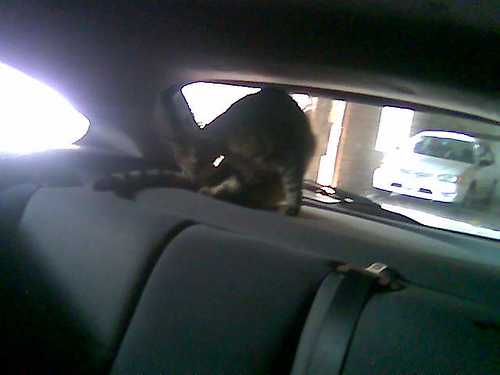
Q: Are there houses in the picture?
A: No, there are no houses.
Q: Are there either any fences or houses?
A: No, there are no houses or fences.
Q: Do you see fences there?
A: No, there are no fences.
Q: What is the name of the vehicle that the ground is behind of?
A: The vehicle is a car.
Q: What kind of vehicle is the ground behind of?
A: The ground is behind the car.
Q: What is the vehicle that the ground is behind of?
A: The vehicle is a car.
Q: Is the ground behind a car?
A: Yes, the ground is behind a car.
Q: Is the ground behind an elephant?
A: No, the ground is behind a car.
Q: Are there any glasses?
A: No, there are no glasses.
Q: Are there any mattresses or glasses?
A: No, there are no glasses or mattresses.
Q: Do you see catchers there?
A: No, there are no catchers.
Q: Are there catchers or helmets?
A: No, there are no catchers or helmets.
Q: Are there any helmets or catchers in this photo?
A: No, there are no catchers or helmets.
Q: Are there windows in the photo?
A: Yes, there is a window.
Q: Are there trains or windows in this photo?
A: Yes, there is a window.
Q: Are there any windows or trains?
A: Yes, there is a window.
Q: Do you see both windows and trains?
A: No, there is a window but no trains.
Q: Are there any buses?
A: No, there are no buses.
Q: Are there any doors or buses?
A: No, there are no buses or doors.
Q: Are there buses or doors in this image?
A: No, there are no buses or doors.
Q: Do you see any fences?
A: No, there are no fences.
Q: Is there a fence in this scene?
A: No, there are no fences.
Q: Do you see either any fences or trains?
A: No, there are no fences or trains.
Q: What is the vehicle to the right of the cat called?
A: The vehicle is a car.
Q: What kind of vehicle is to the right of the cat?
A: The vehicle is a car.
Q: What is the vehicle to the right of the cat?
A: The vehicle is a car.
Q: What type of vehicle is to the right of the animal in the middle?
A: The vehicle is a car.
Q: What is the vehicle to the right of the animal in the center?
A: The vehicle is a car.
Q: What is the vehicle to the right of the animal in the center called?
A: The vehicle is a car.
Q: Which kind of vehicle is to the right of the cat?
A: The vehicle is a car.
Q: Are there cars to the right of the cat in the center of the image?
A: Yes, there is a car to the right of the cat.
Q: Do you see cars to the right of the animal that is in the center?
A: Yes, there is a car to the right of the cat.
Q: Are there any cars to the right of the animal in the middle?
A: Yes, there is a car to the right of the cat.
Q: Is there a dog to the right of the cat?
A: No, there is a car to the right of the cat.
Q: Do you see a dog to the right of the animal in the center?
A: No, there is a car to the right of the cat.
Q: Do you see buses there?
A: No, there are no buses.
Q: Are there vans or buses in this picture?
A: No, there are no buses or vans.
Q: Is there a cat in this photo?
A: Yes, there is a cat.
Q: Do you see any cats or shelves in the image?
A: Yes, there is a cat.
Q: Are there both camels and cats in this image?
A: No, there is a cat but no camels.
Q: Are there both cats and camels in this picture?
A: No, there is a cat but no camels.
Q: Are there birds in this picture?
A: No, there are no birds.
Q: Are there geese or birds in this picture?
A: No, there are no birds or geese.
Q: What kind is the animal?
A: The animal is a cat.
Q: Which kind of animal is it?
A: The animal is a cat.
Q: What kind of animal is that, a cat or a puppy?
A: This is a cat.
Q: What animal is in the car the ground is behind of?
A: The cat is in the car.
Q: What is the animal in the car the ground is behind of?
A: The animal is a cat.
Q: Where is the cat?
A: The cat is in the car.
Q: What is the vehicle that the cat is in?
A: The vehicle is a car.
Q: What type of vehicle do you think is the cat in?
A: The cat is in the car.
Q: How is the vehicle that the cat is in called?
A: The vehicle is a car.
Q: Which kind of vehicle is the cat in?
A: The cat is in the car.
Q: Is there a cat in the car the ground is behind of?
A: Yes, there is a cat in the car.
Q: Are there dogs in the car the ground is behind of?
A: No, there is a cat in the car.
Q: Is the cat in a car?
A: Yes, the cat is in a car.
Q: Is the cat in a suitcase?
A: No, the cat is in a car.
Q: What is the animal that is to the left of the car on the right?
A: The animal is a cat.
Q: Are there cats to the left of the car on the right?
A: Yes, there is a cat to the left of the car.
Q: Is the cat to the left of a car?
A: Yes, the cat is to the left of a car.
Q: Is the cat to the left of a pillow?
A: No, the cat is to the left of a car.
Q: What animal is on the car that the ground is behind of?
A: The animal is a cat.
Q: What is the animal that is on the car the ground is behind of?
A: The animal is a cat.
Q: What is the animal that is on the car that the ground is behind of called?
A: The animal is a cat.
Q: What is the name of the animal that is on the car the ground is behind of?
A: The animal is a cat.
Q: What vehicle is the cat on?
A: The cat is on the car.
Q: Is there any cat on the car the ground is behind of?
A: Yes, there is a cat on the car.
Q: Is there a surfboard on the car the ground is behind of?
A: No, there is a cat on the car.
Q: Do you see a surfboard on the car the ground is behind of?
A: No, there is a cat on the car.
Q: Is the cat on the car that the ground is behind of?
A: Yes, the cat is on the car.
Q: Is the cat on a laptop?
A: No, the cat is on the car.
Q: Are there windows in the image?
A: Yes, there is a window.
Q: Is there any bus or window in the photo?
A: Yes, there is a window.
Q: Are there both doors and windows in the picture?
A: No, there is a window but no doors.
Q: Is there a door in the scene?
A: No, there are no doors.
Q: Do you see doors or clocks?
A: No, there are no doors or clocks.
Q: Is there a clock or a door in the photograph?
A: No, there are no doors or clocks.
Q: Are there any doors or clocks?
A: No, there are no doors or clocks.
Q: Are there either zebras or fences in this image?
A: No, there are no fences or zebras.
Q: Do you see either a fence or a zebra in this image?
A: No, there are no fences or zebras.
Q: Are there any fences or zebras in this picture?
A: No, there are no fences or zebras.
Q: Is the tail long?
A: Yes, the tail is long.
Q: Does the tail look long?
A: Yes, the tail is long.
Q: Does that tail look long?
A: Yes, the tail is long.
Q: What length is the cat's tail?
A: The tail is long.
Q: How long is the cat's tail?
A: The tail is long.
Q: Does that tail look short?
A: No, the tail is long.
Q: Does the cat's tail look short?
A: No, the tail is long.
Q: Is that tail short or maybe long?
A: The tail is long.